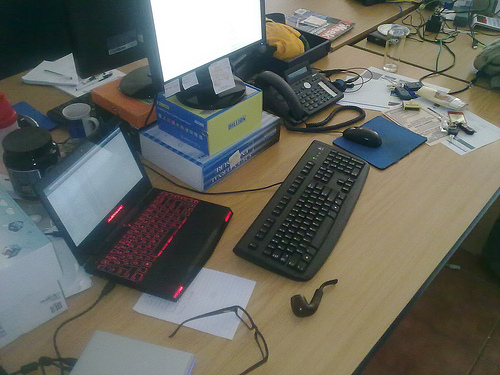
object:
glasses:
[171, 305, 268, 373]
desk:
[0, 0, 495, 371]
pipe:
[289, 279, 341, 318]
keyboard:
[230, 139, 369, 282]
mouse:
[342, 126, 381, 146]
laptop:
[37, 117, 233, 303]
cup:
[61, 101, 100, 141]